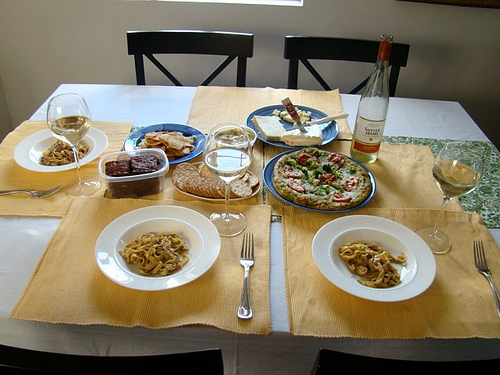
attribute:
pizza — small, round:
[268, 149, 375, 217]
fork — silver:
[237, 231, 256, 323]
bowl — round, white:
[93, 202, 223, 294]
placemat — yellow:
[7, 190, 278, 334]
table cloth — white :
[6, 79, 494, 359]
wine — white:
[55, 116, 85, 131]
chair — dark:
[124, 27, 254, 86]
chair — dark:
[282, 32, 410, 94]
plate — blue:
[262, 147, 374, 213]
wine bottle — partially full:
[351, 32, 391, 163]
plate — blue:
[248, 99, 342, 147]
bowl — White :
[309, 209, 443, 304]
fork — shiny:
[235, 226, 260, 323]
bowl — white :
[82, 197, 246, 309]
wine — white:
[53, 113, 91, 150]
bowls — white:
[88, 204, 440, 311]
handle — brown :
[283, 97, 302, 127]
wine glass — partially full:
[42, 94, 109, 196]